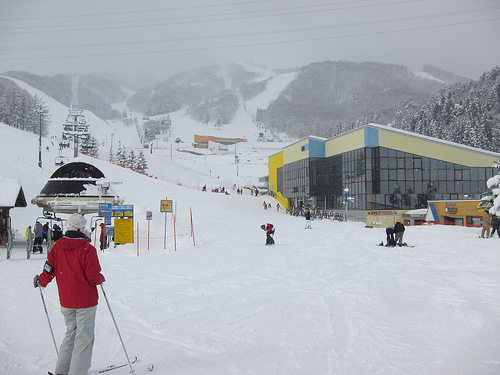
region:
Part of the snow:
[221, 304, 307, 351]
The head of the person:
[63, 211, 89, 233]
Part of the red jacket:
[65, 267, 75, 287]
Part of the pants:
[81, 318, 88, 347]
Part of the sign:
[101, 206, 111, 217]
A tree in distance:
[7, 95, 24, 120]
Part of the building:
[342, 137, 360, 146]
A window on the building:
[374, 144, 391, 158]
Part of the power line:
[184, 32, 201, 43]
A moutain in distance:
[226, 68, 275, 80]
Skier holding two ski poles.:
[28, 210, 154, 372]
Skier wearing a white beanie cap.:
[31, 202, 155, 374]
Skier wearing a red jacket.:
[30, 223, 156, 373]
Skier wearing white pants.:
[31, 214, 158, 374]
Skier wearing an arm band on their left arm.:
[31, 220, 153, 374]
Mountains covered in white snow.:
[0, 50, 499, 138]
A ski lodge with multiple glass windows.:
[258, 123, 498, 228]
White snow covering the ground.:
[2, 120, 498, 372]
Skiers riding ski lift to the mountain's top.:
[2, 142, 133, 258]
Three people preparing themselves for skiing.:
[256, 215, 418, 254]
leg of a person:
[48, 314, 77, 374]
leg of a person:
[68, 308, 105, 364]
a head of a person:
[60, 207, 102, 240]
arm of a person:
[30, 250, 81, 295]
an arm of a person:
[88, 250, 113, 278]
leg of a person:
[388, 227, 404, 248]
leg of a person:
[473, 225, 487, 235]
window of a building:
[282, 165, 294, 173]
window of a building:
[286, 172, 301, 189]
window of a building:
[339, 165, 353, 173]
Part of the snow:
[218, 268, 280, 324]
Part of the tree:
[13, 96, 43, 130]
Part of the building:
[338, 137, 364, 147]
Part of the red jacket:
[63, 259, 79, 284]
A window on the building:
[373, 149, 390, 159]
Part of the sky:
[29, 3, 56, 11]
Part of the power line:
[216, 31, 234, 41]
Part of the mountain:
[268, 74, 336, 87]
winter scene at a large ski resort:
[1, 2, 496, 373]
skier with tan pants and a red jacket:
[30, 210, 152, 374]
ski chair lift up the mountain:
[53, 68, 96, 162]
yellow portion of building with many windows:
[265, 152, 293, 213]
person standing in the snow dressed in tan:
[476, 208, 494, 240]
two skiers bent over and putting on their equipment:
[382, 220, 408, 250]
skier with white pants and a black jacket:
[302, 208, 315, 232]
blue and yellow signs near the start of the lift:
[96, 197, 175, 252]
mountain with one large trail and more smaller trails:
[133, 57, 459, 150]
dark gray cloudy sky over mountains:
[1, 3, 493, 70]